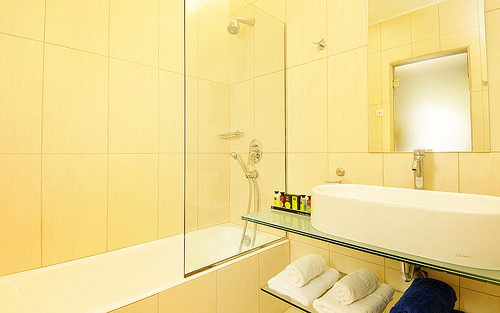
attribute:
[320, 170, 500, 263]
sink — white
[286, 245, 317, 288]
towel — white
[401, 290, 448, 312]
towel — blue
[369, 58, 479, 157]
mirror — wall-mounted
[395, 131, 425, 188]
faucet — chrome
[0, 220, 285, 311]
tub — white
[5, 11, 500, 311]
bathroom — clean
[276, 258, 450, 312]
towels — white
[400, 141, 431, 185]
tap — metallic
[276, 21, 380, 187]
wall — tiled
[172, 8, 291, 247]
glass — transparent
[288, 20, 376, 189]
tile — white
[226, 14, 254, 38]
shower head — silver